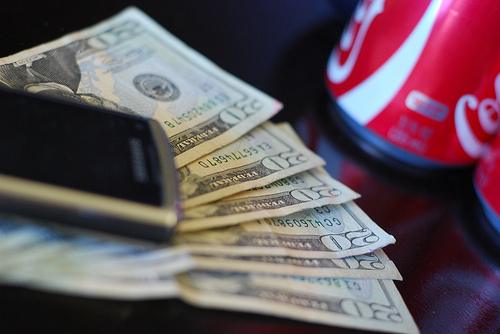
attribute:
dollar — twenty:
[186, 166, 366, 240]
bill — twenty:
[192, 90, 302, 202]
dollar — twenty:
[1, 5, 282, 170]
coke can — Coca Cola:
[311, 64, 473, 182]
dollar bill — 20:
[11, 7, 300, 158]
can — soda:
[284, 3, 498, 206]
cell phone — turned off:
[13, 70, 221, 275]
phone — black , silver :
[3, 74, 188, 239]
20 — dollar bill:
[214, 183, 432, 322]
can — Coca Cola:
[323, 1, 498, 218]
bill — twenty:
[60, 202, 395, 278]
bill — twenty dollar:
[53, 248, 411, 286]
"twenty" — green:
[290, 180, 343, 204]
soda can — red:
[322, 0, 493, 175]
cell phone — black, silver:
[4, 87, 179, 242]